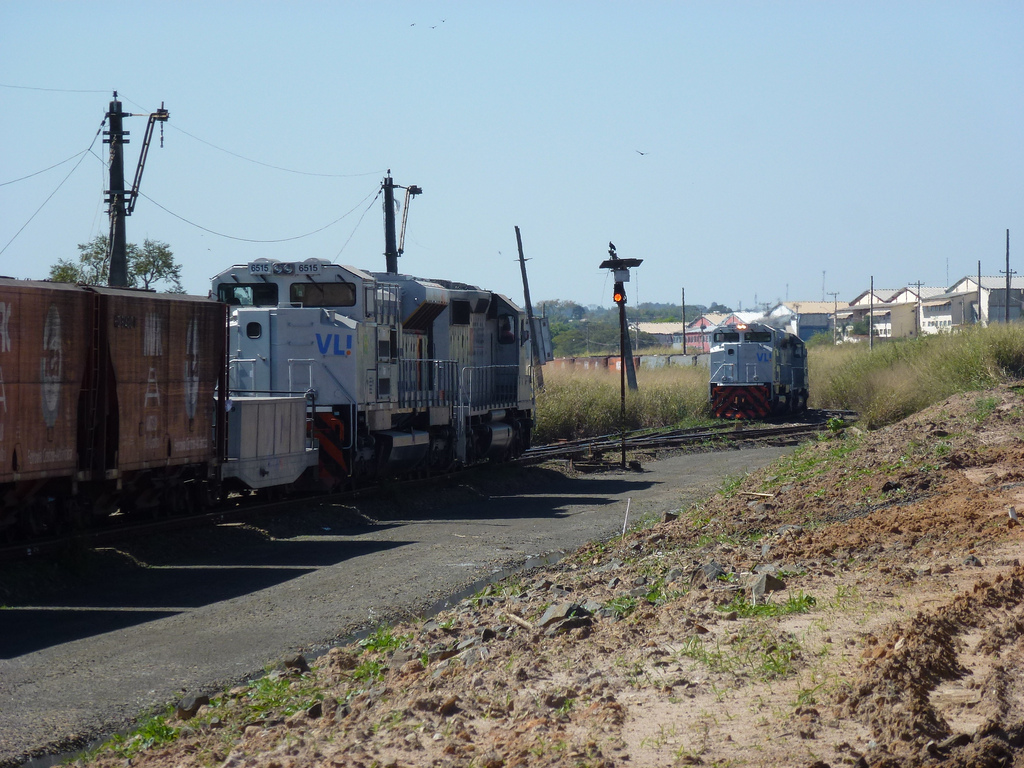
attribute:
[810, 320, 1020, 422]
grass — green